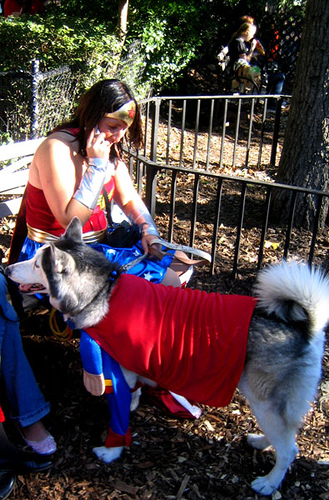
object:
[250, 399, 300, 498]
leg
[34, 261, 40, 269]
eye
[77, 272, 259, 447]
cape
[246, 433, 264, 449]
paw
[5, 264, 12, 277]
nose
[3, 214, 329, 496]
dog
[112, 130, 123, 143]
nose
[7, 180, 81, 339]
bench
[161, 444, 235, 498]
mulch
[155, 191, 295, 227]
shadow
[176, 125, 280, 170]
sunlight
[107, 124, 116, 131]
eye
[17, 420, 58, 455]
pink shoe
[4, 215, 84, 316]
head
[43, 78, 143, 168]
hair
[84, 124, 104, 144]
phone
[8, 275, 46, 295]
mouth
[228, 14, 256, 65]
kid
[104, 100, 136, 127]
head band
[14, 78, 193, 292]
costumed woman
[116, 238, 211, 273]
leash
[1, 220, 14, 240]
cape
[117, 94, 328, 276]
fence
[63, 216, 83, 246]
ear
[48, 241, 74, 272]
ear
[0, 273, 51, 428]
jeans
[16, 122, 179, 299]
costume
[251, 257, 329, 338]
tail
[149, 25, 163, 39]
leaves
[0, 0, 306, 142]
bush